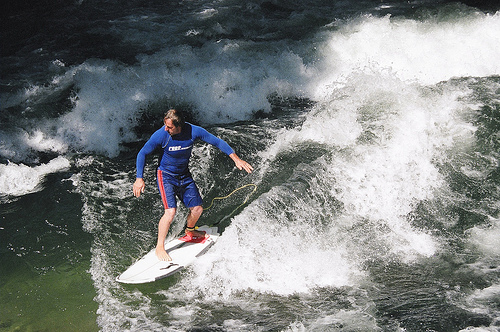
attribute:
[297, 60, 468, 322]
waves — white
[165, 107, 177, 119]
hair — wet, brown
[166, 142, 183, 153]
writing — white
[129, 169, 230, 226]
shorts — blue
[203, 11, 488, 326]
water — white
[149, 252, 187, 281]
foot — bare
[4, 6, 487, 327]
water — choppy, white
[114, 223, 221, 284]
surfboard — white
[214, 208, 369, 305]
waves — white, crashing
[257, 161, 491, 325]
waves — splashing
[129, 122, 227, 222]
shirt — blue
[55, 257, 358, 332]
water — white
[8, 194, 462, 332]
water — white